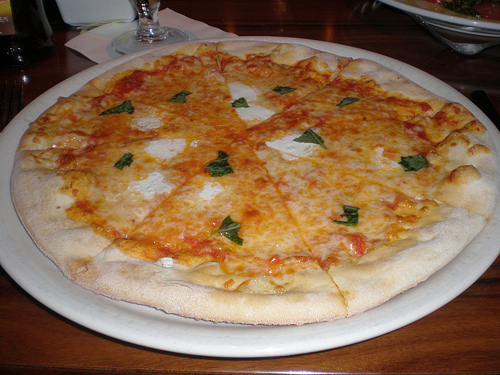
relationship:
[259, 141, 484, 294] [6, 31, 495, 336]
slice of pizza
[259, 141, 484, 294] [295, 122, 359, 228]
slice has basil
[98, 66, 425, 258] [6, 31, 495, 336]
cheese on pizza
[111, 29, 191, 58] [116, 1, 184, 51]
bottom of glass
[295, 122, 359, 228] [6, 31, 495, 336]
basil used on pizza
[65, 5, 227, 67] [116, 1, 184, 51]
napkin under a glass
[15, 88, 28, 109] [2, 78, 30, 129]
part of a fork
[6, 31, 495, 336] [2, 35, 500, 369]
pizza on a plate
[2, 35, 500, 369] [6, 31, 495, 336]
plate under pizza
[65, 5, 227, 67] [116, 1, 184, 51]
napkin under glass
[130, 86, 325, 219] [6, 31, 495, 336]
topping on pizza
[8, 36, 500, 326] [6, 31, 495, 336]
topping covering pizza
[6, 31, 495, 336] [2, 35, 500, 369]
pizza sitting on a plate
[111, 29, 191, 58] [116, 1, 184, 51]
bottom of a glass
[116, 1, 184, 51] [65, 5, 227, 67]
glass sitting on a napkin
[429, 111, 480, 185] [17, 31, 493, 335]
bubbles on crust